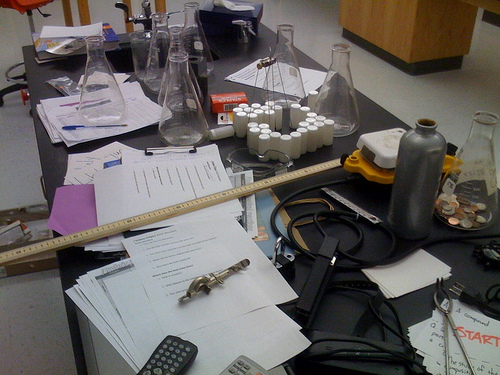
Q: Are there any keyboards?
A: No, there are no keyboards.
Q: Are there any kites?
A: No, there are no kites.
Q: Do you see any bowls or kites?
A: No, there are no kites or bowls.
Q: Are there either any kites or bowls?
A: No, there are no kites or bowls.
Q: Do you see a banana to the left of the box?
A: No, there are papers to the left of the box.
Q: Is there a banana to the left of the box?
A: No, there are papers to the left of the box.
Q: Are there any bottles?
A: Yes, there is a bottle.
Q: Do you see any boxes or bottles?
A: Yes, there is a bottle.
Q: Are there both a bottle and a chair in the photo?
A: Yes, there are both a bottle and a chair.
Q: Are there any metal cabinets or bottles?
A: Yes, there is a metal bottle.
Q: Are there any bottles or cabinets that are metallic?
A: Yes, the bottle is metallic.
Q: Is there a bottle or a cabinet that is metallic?
A: Yes, the bottle is metallic.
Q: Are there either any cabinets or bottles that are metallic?
A: Yes, the bottle is metallic.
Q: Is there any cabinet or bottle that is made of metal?
A: Yes, the bottle is made of metal.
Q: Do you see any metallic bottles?
A: Yes, there is a metal bottle.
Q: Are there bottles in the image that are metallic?
A: Yes, there is a bottle that is metallic.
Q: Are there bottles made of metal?
A: Yes, there is a bottle that is made of metal.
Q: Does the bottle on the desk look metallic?
A: Yes, the bottle is metallic.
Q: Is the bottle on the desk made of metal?
A: Yes, the bottle is made of metal.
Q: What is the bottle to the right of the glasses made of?
A: The bottle is made of metal.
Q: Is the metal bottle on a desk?
A: Yes, the bottle is on a desk.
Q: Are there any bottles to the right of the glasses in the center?
A: Yes, there is a bottle to the right of the glasses.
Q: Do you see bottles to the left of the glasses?
A: No, the bottle is to the right of the glasses.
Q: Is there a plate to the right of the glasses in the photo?
A: No, there is a bottle to the right of the glasses.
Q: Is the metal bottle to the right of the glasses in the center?
A: Yes, the bottle is to the right of the glasses.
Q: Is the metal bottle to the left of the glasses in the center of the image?
A: No, the bottle is to the right of the glasses.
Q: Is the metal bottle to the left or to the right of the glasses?
A: The bottle is to the right of the glasses.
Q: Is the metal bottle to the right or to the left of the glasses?
A: The bottle is to the right of the glasses.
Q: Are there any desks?
A: Yes, there is a desk.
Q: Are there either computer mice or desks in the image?
A: Yes, there is a desk.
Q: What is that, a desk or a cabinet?
A: That is a desk.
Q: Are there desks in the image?
A: Yes, there is a desk.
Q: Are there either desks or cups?
A: Yes, there is a desk.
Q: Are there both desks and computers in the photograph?
A: No, there is a desk but no computers.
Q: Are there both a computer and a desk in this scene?
A: No, there is a desk but no computers.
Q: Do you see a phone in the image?
A: No, there are no phones.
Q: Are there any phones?
A: No, there are no phones.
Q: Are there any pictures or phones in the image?
A: No, there are no phones or pictures.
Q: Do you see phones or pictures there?
A: No, there are no phones or pictures.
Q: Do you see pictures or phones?
A: No, there are no phones or pictures.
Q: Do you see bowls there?
A: No, there are no bowls.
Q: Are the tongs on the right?
A: Yes, the tongs are on the right of the image.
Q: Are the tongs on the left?
A: No, the tongs are on the right of the image.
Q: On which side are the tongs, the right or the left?
A: The tongs are on the right of the image.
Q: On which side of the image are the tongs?
A: The tongs are on the right of the image.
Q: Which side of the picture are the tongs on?
A: The tongs are on the right of the image.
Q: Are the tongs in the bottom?
A: Yes, the tongs are in the bottom of the image.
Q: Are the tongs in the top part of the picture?
A: No, the tongs are in the bottom of the image.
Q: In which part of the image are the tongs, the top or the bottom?
A: The tongs are in the bottom of the image.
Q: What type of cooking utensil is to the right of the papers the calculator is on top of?
A: The cooking utensils are tongs.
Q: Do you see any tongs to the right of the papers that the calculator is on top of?
A: Yes, there are tongs to the right of the papers.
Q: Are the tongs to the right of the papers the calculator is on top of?
A: Yes, the tongs are to the right of the papers.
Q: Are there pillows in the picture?
A: No, there are no pillows.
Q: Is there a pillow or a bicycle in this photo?
A: No, there are no pillows or bicycles.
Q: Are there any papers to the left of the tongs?
A: Yes, there are papers to the left of the tongs.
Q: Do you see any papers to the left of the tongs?
A: Yes, there are papers to the left of the tongs.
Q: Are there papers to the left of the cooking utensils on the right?
A: Yes, there are papers to the left of the tongs.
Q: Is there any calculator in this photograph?
A: Yes, there is a calculator.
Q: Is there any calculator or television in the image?
A: Yes, there is a calculator.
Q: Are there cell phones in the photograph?
A: No, there are no cell phones.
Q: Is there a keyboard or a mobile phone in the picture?
A: No, there are no cell phones or keyboards.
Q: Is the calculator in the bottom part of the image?
A: Yes, the calculator is in the bottom of the image.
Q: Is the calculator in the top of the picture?
A: No, the calculator is in the bottom of the image.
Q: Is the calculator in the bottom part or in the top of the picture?
A: The calculator is in the bottom of the image.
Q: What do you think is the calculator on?
A: The calculator is on the desk.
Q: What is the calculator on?
A: The calculator is on the desk.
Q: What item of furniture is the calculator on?
A: The calculator is on the desk.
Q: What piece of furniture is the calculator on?
A: The calculator is on the desk.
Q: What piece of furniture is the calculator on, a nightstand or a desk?
A: The calculator is on a desk.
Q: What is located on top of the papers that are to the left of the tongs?
A: The calculator is on top of the papers.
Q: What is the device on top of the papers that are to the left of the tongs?
A: The device is a calculator.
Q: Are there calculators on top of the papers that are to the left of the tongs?
A: Yes, there is a calculator on top of the papers.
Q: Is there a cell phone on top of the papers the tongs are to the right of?
A: No, there is a calculator on top of the papers.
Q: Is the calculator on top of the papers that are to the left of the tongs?
A: Yes, the calculator is on top of the papers.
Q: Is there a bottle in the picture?
A: Yes, there is a bottle.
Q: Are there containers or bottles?
A: Yes, there is a bottle.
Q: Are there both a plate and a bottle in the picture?
A: No, there is a bottle but no plates.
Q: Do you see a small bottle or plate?
A: Yes, there is a small bottle.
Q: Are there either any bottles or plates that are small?
A: Yes, the bottle is small.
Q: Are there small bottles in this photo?
A: Yes, there is a small bottle.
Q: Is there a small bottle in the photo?
A: Yes, there is a small bottle.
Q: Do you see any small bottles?
A: Yes, there is a small bottle.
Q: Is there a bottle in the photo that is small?
A: Yes, there is a bottle that is small.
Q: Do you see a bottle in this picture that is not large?
A: Yes, there is a small bottle.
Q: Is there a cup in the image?
A: No, there are no cups.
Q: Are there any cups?
A: No, there are no cups.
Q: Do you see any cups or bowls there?
A: No, there are no cups or bowls.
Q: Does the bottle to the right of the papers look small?
A: Yes, the bottle is small.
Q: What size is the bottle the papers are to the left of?
A: The bottle is small.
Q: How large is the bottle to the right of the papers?
A: The bottle is small.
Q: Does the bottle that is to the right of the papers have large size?
A: No, the bottle is small.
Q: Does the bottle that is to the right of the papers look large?
A: No, the bottle is small.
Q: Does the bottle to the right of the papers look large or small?
A: The bottle is small.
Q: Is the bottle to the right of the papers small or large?
A: The bottle is small.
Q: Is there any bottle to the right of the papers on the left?
A: Yes, there is a bottle to the right of the papers.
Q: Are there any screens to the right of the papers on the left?
A: No, there is a bottle to the right of the papers.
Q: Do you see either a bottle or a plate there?
A: Yes, there is a bottle.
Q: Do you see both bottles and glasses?
A: Yes, there are both a bottle and glasses.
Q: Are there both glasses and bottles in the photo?
A: Yes, there are both a bottle and glasses.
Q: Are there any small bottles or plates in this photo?
A: Yes, there is a small bottle.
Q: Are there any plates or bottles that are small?
A: Yes, the bottle is small.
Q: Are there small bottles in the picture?
A: Yes, there is a small bottle.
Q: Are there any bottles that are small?
A: Yes, there is a bottle that is small.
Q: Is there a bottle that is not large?
A: Yes, there is a small bottle.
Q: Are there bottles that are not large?
A: Yes, there is a small bottle.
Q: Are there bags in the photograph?
A: No, there are no bags.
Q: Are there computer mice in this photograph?
A: No, there are no computer mice.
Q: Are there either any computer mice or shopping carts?
A: No, there are no computer mice or shopping carts.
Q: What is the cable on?
A: The cable is on the desk.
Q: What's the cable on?
A: The cable is on the desk.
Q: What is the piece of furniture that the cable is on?
A: The piece of furniture is a desk.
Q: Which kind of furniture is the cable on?
A: The cable is on the desk.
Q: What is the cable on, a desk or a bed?
A: The cable is on a desk.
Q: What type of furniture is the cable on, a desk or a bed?
A: The cable is on a desk.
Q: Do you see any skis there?
A: No, there are no skis.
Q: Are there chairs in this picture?
A: Yes, there is a chair.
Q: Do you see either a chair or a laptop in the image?
A: Yes, there is a chair.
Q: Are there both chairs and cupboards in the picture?
A: No, there is a chair but no cupboards.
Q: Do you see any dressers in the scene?
A: No, there are no dressers.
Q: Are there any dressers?
A: No, there are no dressers.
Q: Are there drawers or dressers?
A: No, there are no dressers or drawers.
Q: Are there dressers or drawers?
A: No, there are no dressers or drawers.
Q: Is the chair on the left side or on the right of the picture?
A: The chair is on the left of the image.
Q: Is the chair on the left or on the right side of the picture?
A: The chair is on the left of the image.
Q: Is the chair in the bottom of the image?
A: No, the chair is in the top of the image.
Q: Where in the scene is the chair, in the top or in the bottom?
A: The chair is in the top of the image.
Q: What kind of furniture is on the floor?
A: The piece of furniture is a chair.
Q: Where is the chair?
A: The chair is on the floor.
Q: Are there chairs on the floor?
A: Yes, there is a chair on the floor.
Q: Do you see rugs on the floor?
A: No, there is a chair on the floor.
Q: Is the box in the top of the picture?
A: Yes, the box is in the top of the image.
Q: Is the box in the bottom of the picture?
A: No, the box is in the top of the image.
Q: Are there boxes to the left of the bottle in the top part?
A: Yes, there is a box to the left of the bottle.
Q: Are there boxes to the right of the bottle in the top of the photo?
A: No, the box is to the left of the bottle.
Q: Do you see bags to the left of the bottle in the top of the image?
A: No, there is a box to the left of the bottle.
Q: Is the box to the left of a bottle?
A: Yes, the box is to the left of a bottle.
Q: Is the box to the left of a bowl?
A: No, the box is to the left of a bottle.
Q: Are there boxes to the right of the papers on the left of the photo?
A: Yes, there is a box to the right of the papers.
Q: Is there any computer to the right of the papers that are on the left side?
A: No, there is a box to the right of the papers.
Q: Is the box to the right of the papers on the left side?
A: Yes, the box is to the right of the papers.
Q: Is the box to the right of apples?
A: No, the box is to the right of the papers.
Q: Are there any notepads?
A: No, there are no notepads.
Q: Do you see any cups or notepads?
A: No, there are no notepads or cups.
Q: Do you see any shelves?
A: No, there are no shelves.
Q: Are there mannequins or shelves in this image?
A: No, there are no shelves or mannequins.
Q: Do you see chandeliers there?
A: No, there are no chandeliers.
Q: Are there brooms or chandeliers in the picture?
A: No, there are no chandeliers or brooms.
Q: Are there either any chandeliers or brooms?
A: No, there are no chandeliers or brooms.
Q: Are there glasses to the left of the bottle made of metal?
A: Yes, there are glasses to the left of the bottle.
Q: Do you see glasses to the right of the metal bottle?
A: No, the glasses are to the left of the bottle.